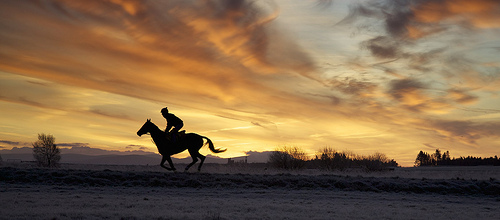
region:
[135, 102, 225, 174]
a person riding a horse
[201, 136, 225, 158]
the horses tail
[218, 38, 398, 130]
the sky is orange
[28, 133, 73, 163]
a tree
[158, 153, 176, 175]
the horses front legs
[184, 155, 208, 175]
the horses back legs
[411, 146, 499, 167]
the bush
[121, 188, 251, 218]
dirt on the ground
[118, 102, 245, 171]
the person is riding a horse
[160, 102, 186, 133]
person riding a horse in against a sunset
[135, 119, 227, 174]
horse running with a person on it's back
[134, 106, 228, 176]
person and horse running against a sunset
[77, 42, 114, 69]
cloud in the sky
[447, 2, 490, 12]
cloud in the sky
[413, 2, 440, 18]
cloud in the sky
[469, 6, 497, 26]
cloud in the sky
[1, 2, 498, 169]
sky during sunset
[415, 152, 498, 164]
field of trees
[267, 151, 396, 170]
field of trees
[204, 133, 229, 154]
The tail of the horse.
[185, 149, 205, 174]
The back legs of the horse.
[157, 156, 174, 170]
The front legs of the horse.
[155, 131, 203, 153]
The body of the horse.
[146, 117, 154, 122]
The ears of the horse.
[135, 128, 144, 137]
The nose and mouth area of the horse.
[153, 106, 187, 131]
The person on the horse's back.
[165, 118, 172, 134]
The arms of the person on the horse's back.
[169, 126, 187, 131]
The legs of the person on the back of the horse.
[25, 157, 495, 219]
The ground where the horse is running.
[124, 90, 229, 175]
person riding a horse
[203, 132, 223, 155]
a tail on the horse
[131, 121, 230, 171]
the horse is standing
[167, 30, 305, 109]
the sky is orange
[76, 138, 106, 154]
the clouds in the sky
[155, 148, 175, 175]
the horses front legs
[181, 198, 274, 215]
sand on the ground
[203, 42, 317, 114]
the sky is the sky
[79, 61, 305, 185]
a man riding a horse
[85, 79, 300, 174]
man and horse running in front of an evening sky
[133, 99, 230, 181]
a man riding a horse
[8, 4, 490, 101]
a beautiful sky at sunset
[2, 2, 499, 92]
a beautiful sky at sunrise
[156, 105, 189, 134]
a man riding a horse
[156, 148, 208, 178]
the legs of a horse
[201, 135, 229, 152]
the tail of a horse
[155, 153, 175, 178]
the front legs of a horse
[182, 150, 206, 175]
the rear legs of a horse